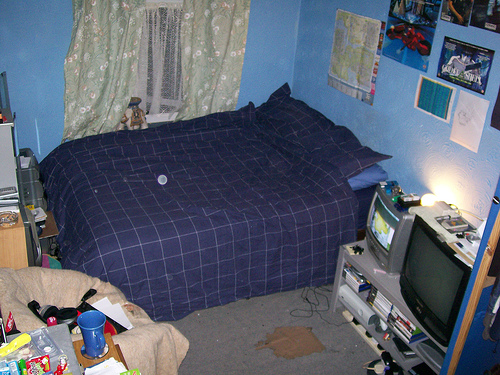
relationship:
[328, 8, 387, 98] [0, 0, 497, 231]
map on wall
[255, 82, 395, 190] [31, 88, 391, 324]
pillow on bed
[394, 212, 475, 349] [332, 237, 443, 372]
tv on shelf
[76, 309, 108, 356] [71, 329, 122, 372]
blue cup on table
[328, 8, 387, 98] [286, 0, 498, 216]
map attached to wall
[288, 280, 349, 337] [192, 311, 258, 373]
wires on carpet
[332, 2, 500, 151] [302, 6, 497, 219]
posters on wall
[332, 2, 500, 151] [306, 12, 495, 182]
posters on wall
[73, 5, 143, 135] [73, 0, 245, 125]
curtain on window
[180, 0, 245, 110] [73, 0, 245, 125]
curtain on window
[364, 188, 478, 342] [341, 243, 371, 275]
televisions on shelf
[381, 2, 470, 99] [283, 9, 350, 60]
posters are on wall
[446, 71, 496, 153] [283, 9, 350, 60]
papers are on wall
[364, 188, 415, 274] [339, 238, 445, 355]
televisions on shelf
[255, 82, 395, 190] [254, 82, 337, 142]
pillow in case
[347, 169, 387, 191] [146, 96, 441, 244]
pillow on bed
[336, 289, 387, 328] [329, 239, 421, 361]
game system in stand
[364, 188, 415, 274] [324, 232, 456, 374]
televisions on stand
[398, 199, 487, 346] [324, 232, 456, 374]
tv on stand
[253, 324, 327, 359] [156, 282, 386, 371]
stain on floor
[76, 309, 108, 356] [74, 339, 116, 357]
blue cup on a cd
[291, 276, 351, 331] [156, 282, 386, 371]
wire draped onto floor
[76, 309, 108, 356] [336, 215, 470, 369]
blue cup on table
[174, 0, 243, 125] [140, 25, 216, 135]
curtain on window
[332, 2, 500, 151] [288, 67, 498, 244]
posters on wall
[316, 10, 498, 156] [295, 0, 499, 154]
pictures on wall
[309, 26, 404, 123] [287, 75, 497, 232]
map on wall